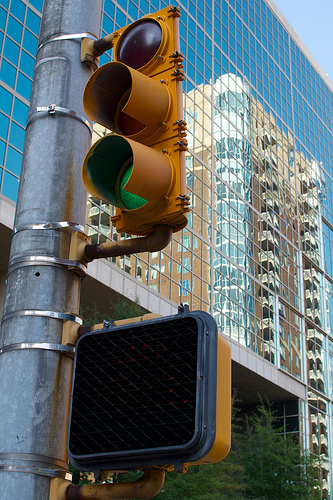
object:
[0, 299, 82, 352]
band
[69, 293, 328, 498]
tree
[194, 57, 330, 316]
windows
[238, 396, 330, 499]
plant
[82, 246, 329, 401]
concrete face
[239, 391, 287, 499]
plants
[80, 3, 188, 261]
traffic light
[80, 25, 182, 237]
signal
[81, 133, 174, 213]
traffic light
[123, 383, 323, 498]
tree tops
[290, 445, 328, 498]
plants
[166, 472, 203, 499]
plants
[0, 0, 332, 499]
building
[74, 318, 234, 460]
sign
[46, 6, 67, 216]
grey pole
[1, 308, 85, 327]
clip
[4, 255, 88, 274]
clip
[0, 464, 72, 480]
clip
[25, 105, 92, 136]
clip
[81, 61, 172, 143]
traffic light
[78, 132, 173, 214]
green light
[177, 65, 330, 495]
reflection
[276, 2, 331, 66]
sky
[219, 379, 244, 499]
plants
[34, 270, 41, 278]
hole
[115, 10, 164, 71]
light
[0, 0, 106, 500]
pole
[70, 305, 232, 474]
building